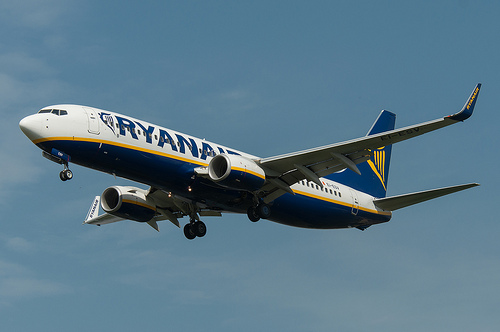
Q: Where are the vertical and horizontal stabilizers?
A: On the tail section of the plane.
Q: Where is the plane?
A: In the air.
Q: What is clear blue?
A: The sky.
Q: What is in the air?
A: The plane.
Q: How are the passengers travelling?
A: By airplane.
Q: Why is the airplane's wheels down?
A: Getting ready to land.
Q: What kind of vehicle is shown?
A: Airplane.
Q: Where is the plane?
A: Sky.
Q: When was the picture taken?
A: During the daytime.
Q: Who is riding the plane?
A: Passengers.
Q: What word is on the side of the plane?
A: Ryanair.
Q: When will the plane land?
A: End of flight.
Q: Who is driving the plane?
A: Pilot.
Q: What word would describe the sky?
A: Blue.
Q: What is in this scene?
A: Jet plane in flight.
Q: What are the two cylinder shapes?
A: Engines.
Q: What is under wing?
A: Jet engine.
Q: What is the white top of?
A: Plane.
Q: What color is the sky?
A: Blue.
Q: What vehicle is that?
A: Airplane.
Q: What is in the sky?
A: Plane.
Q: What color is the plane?
A: White.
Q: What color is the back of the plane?
A: Blue and yellow.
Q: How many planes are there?
A: One.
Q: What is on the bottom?
A: Wheels.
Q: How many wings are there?
A: Two.